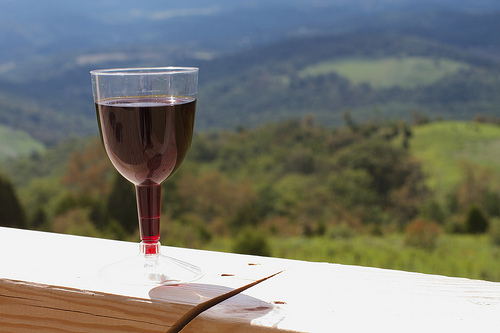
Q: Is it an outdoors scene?
A: Yes, it is outdoors.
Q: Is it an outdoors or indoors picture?
A: It is outdoors.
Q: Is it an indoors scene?
A: No, it is outdoors.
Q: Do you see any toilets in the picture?
A: No, there are no toilets.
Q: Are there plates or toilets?
A: No, there are no toilets or plates.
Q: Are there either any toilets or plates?
A: No, there are no toilets or plates.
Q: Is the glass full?
A: Yes, the glass is full.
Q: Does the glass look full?
A: Yes, the glass is full.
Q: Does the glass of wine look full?
A: Yes, the glass is full.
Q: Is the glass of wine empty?
A: No, the glass is full.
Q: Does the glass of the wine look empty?
A: No, the glass is full.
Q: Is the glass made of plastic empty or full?
A: The glass is full.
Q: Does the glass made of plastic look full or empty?
A: The glass is full.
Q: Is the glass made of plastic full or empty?
A: The glass is full.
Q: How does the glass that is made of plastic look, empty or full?
A: The glass is full.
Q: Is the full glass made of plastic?
A: Yes, the glass is made of plastic.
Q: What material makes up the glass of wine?
A: The glass is made of plastic.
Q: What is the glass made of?
A: The glass is made of plastic.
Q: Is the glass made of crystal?
A: No, the glass is made of plastic.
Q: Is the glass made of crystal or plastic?
A: The glass is made of plastic.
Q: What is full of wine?
A: The glass is full of wine.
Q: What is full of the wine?
A: The glass is full of wine.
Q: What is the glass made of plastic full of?
A: The glass is full of wine.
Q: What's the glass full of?
A: The glass is full of wine.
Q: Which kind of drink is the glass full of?
A: The glass is full of wine.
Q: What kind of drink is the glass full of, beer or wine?
A: The glass is full of wine.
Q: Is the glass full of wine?
A: Yes, the glass is full of wine.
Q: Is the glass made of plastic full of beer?
A: No, the glass is full of wine.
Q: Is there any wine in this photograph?
A: Yes, there is wine.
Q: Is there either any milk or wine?
A: Yes, there is wine.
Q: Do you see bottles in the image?
A: No, there are no bottles.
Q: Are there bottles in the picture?
A: No, there are no bottles.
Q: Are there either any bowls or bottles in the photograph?
A: No, there are no bottles or bowls.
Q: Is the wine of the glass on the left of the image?
A: Yes, the wine is on the left of the image.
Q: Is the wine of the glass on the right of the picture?
A: No, the wine is on the left of the image.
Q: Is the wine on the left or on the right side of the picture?
A: The wine is on the left of the image.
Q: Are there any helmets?
A: No, there are no helmets.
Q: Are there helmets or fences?
A: No, there are no helmets or fences.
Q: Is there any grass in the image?
A: Yes, there is grass.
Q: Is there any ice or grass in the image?
A: Yes, there is grass.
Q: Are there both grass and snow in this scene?
A: No, there is grass but no snow.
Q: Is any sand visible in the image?
A: No, there is no sand.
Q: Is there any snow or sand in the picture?
A: No, there are no sand or snow.